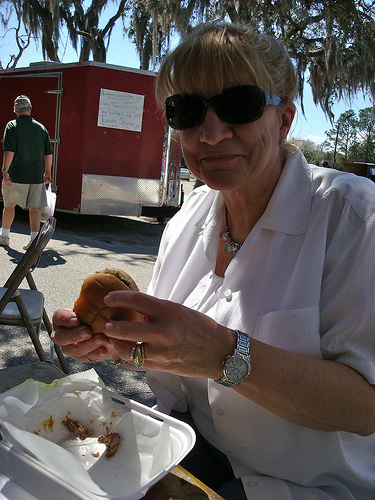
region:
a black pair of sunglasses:
[145, 77, 305, 138]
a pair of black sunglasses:
[138, 70, 301, 132]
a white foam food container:
[5, 366, 204, 494]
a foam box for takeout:
[31, 373, 200, 498]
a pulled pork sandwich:
[63, 248, 147, 336]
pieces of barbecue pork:
[57, 405, 125, 458]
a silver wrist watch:
[208, 315, 272, 397]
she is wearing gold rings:
[111, 332, 167, 375]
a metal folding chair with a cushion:
[8, 201, 80, 391]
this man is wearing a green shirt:
[8, 83, 79, 238]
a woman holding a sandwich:
[51, 234, 181, 378]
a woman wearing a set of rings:
[128, 332, 156, 373]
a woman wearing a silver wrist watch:
[217, 322, 264, 399]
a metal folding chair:
[0, 216, 64, 332]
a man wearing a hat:
[7, 89, 30, 123]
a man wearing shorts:
[0, 184, 54, 219]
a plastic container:
[5, 401, 163, 494]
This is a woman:
[55, 25, 367, 406]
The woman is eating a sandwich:
[46, 268, 184, 371]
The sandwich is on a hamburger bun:
[59, 269, 164, 340]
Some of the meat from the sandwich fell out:
[53, 405, 129, 462]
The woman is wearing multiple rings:
[122, 333, 149, 367]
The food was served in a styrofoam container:
[1, 366, 182, 491]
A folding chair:
[4, 220, 74, 371]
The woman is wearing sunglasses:
[158, 78, 309, 132]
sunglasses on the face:
[155, 82, 298, 140]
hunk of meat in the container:
[88, 426, 129, 459]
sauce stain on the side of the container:
[34, 412, 61, 435]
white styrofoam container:
[1, 367, 201, 499]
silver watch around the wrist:
[211, 323, 255, 392]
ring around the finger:
[127, 345, 147, 371]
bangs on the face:
[154, 36, 262, 102]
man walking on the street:
[0, 90, 75, 267]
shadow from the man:
[4, 238, 70, 273]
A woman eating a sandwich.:
[30, 20, 361, 496]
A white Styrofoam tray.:
[3, 368, 213, 497]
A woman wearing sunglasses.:
[157, 25, 311, 190]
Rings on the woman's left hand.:
[124, 341, 155, 370]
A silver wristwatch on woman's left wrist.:
[204, 314, 265, 395]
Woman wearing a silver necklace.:
[143, 21, 324, 270]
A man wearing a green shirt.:
[1, 84, 60, 207]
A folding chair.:
[0, 217, 63, 365]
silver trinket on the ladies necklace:
[214, 224, 230, 240]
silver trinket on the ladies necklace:
[220, 238, 234, 254]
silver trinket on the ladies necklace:
[228, 238, 240, 252]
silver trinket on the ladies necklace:
[232, 243, 240, 254]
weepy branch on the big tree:
[38, 9, 56, 62]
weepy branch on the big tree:
[307, 58, 322, 104]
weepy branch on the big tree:
[315, 65, 337, 125]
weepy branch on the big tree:
[320, 0, 333, 39]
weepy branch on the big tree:
[294, 54, 310, 122]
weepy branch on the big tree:
[147, 10, 159, 63]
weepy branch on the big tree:
[157, 4, 179, 49]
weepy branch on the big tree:
[60, 2, 78, 52]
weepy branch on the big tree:
[72, 1, 86, 29]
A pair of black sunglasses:
[153, 77, 291, 137]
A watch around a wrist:
[203, 323, 256, 393]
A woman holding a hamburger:
[35, 12, 365, 421]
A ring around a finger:
[116, 332, 148, 373]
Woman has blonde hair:
[144, 15, 303, 199]